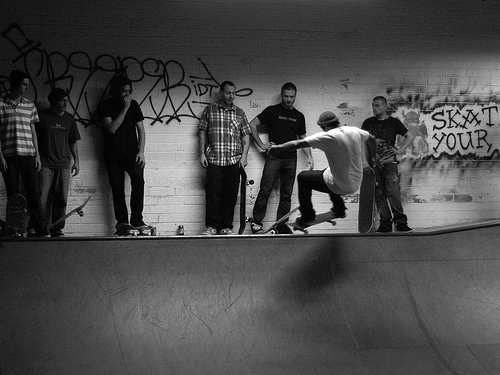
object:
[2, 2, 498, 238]
wall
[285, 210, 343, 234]
skateboard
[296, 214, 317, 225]
feet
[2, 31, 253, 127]
graffiti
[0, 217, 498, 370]
ramp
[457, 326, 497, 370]
patch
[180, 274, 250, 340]
scuff mark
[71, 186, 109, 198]
brick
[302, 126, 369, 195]
shirt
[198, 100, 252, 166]
shirt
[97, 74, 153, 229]
man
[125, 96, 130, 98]
mouth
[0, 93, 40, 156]
shirt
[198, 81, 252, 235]
man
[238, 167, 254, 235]
skateboard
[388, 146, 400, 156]
hand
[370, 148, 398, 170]
hip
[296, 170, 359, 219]
pants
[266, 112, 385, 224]
man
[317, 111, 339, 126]
hat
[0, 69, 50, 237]
men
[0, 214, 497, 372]
skateboard ramp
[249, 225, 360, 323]
shadow